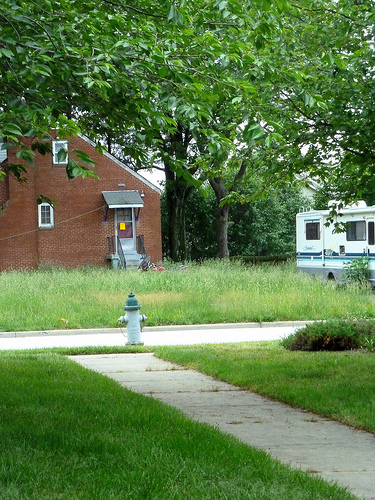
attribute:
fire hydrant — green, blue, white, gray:
[118, 290, 152, 345]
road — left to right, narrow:
[0, 319, 328, 358]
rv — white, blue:
[291, 191, 373, 293]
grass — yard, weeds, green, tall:
[4, 263, 372, 327]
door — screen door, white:
[101, 184, 145, 268]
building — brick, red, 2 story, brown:
[0, 110, 164, 269]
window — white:
[35, 201, 56, 228]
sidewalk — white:
[69, 347, 373, 499]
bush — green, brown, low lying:
[289, 315, 362, 352]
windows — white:
[31, 136, 70, 236]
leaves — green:
[3, 1, 372, 169]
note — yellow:
[119, 220, 128, 232]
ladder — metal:
[295, 203, 311, 216]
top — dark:
[124, 292, 141, 310]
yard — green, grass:
[5, 319, 374, 499]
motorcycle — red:
[135, 259, 166, 273]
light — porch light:
[137, 186, 150, 203]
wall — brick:
[73, 151, 165, 271]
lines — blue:
[298, 250, 374, 270]